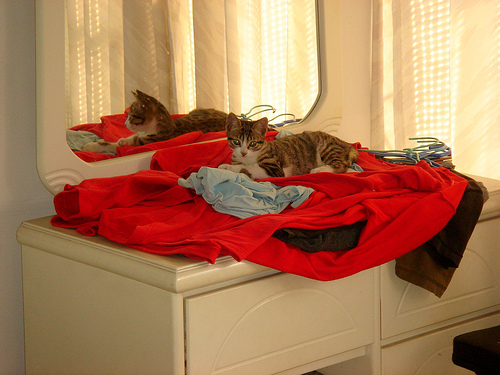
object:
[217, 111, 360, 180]
cat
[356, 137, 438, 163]
hangers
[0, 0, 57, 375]
wall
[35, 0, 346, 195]
frame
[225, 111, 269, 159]
cat head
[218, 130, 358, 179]
body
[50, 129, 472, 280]
fabric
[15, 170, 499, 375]
dresser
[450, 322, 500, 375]
stool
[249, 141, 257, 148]
eyes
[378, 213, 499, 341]
dresser drawer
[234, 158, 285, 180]
leg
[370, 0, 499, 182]
curtain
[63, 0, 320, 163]
mirror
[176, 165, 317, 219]
cloth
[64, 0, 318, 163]
reflection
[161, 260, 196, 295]
corner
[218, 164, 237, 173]
paw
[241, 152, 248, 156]
nose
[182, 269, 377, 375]
drawer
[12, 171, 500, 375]
cabinet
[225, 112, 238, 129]
ear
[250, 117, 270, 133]
ear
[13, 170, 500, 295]
counter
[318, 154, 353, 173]
leg